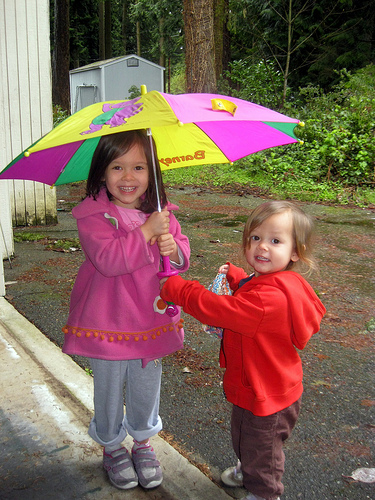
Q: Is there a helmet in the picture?
A: No, there are no helmets.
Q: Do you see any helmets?
A: No, there are no helmets.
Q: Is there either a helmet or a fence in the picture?
A: No, there are no helmets or fences.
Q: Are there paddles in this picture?
A: No, there are no paddles.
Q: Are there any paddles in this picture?
A: No, there are no paddles.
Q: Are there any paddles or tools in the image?
A: No, there are no paddles or tools.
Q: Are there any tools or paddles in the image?
A: No, there are no paddles or tools.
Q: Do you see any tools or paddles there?
A: No, there are no paddles or tools.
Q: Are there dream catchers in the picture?
A: No, there are no dream catchers.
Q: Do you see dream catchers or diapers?
A: No, there are no dream catchers or diapers.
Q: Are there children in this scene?
A: Yes, there is a child.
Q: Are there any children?
A: Yes, there is a child.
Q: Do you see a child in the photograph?
A: Yes, there is a child.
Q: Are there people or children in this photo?
A: Yes, there is a child.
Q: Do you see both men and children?
A: No, there is a child but no men.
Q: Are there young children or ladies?
A: Yes, there is a young child.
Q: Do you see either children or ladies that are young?
A: Yes, the child is young.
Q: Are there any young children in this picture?
A: Yes, there is a young child.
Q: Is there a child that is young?
A: Yes, there is a child that is young.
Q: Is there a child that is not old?
A: Yes, there is an young child.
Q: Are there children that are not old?
A: Yes, there is an young child.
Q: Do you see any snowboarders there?
A: No, there are no snowboarders.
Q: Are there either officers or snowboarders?
A: No, there are no snowboarders or officers.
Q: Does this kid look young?
A: Yes, the kid is young.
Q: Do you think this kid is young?
A: Yes, the kid is young.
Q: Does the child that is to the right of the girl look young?
A: Yes, the child is young.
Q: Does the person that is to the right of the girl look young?
A: Yes, the child is young.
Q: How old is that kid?
A: The kid is young.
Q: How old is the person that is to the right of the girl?
A: The kid is young.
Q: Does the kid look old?
A: No, the kid is young.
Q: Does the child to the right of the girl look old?
A: No, the kid is young.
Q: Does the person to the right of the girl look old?
A: No, the kid is young.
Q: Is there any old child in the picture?
A: No, there is a child but he is young.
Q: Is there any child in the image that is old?
A: No, there is a child but he is young.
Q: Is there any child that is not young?
A: No, there is a child but he is young.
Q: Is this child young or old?
A: The child is young.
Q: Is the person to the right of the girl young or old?
A: The child is young.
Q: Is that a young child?
A: Yes, that is a young child.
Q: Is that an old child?
A: No, that is a young child.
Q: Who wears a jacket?
A: The kid wears a jacket.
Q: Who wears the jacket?
A: The kid wears a jacket.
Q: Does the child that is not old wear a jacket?
A: Yes, the child wears a jacket.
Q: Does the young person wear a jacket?
A: Yes, the child wears a jacket.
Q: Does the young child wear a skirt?
A: No, the child wears a jacket.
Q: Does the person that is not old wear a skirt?
A: No, the child wears a jacket.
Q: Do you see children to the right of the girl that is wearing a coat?
A: Yes, there is a child to the right of the girl.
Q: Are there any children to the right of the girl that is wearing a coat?
A: Yes, there is a child to the right of the girl.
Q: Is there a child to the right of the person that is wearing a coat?
A: Yes, there is a child to the right of the girl.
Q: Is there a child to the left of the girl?
A: No, the child is to the right of the girl.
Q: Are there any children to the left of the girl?
A: No, the child is to the right of the girl.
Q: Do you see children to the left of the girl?
A: No, the child is to the right of the girl.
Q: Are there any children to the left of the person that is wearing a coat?
A: No, the child is to the right of the girl.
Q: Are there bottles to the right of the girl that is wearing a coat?
A: No, there is a child to the right of the girl.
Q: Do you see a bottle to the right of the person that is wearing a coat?
A: No, there is a child to the right of the girl.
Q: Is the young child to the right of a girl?
A: Yes, the kid is to the right of a girl.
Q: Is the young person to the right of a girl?
A: Yes, the kid is to the right of a girl.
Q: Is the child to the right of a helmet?
A: No, the child is to the right of a girl.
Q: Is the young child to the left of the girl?
A: No, the child is to the right of the girl.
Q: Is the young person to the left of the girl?
A: No, the child is to the right of the girl.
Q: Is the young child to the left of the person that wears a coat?
A: No, the child is to the right of the girl.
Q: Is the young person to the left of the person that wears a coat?
A: No, the child is to the right of the girl.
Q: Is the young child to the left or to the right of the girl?
A: The child is to the right of the girl.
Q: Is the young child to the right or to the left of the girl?
A: The child is to the right of the girl.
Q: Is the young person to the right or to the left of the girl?
A: The child is to the right of the girl.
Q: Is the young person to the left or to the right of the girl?
A: The child is to the right of the girl.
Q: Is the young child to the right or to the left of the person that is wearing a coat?
A: The child is to the right of the girl.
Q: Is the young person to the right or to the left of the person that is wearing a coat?
A: The child is to the right of the girl.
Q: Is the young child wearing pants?
A: Yes, the child is wearing pants.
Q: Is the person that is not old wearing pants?
A: Yes, the child is wearing pants.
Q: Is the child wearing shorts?
A: No, the child is wearing pants.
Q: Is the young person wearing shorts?
A: No, the child is wearing pants.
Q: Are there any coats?
A: Yes, there is a coat.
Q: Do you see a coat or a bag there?
A: Yes, there is a coat.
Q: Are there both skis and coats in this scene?
A: No, there is a coat but no skis.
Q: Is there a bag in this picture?
A: No, there are no bags.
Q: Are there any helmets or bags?
A: No, there are no bags or helmets.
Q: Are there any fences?
A: No, there are no fences.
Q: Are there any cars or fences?
A: No, there are no fences or cars.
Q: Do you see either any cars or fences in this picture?
A: No, there are no fences or cars.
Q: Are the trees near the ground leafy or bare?
A: The trees are leafy.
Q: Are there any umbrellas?
A: Yes, there is an umbrella.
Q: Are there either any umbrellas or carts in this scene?
A: Yes, there is an umbrella.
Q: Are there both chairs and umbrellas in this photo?
A: No, there is an umbrella but no chairs.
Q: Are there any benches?
A: No, there are no benches.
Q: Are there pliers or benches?
A: No, there are no benches or pliers.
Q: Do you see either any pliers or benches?
A: No, there are no benches or pliers.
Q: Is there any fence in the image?
A: No, there are no fences.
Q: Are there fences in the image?
A: No, there are no fences.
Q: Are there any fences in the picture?
A: No, there are no fences.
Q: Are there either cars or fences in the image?
A: No, there are no fences or cars.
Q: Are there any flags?
A: No, there are no flags.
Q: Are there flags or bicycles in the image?
A: No, there are no flags or bicycles.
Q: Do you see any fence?
A: No, there are no fences.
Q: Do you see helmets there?
A: No, there are no helmets.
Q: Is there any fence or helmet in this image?
A: No, there are no helmets or fences.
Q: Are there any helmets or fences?
A: No, there are no helmets or fences.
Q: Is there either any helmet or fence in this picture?
A: No, there are no helmets or fences.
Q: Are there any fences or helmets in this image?
A: No, there are no helmets or fences.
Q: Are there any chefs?
A: No, there are no chefs.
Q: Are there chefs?
A: No, there are no chefs.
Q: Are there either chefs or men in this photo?
A: No, there are no chefs or men.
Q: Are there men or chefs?
A: No, there are no chefs or men.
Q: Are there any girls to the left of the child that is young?
A: Yes, there is a girl to the left of the child.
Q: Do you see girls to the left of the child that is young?
A: Yes, there is a girl to the left of the child.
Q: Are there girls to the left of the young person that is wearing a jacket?
A: Yes, there is a girl to the left of the child.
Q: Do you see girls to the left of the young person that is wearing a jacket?
A: Yes, there is a girl to the left of the child.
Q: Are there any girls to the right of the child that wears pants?
A: No, the girl is to the left of the child.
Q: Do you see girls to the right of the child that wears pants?
A: No, the girl is to the left of the child.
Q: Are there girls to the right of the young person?
A: No, the girl is to the left of the child.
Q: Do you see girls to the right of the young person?
A: No, the girl is to the left of the child.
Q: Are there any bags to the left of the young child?
A: No, there is a girl to the left of the kid.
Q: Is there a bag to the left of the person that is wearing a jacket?
A: No, there is a girl to the left of the kid.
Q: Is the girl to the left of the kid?
A: Yes, the girl is to the left of the kid.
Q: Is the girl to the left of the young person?
A: Yes, the girl is to the left of the kid.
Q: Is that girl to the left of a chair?
A: No, the girl is to the left of the kid.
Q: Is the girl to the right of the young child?
A: No, the girl is to the left of the child.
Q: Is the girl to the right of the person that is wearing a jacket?
A: No, the girl is to the left of the child.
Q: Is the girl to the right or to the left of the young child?
A: The girl is to the left of the child.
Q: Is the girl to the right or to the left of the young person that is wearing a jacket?
A: The girl is to the left of the child.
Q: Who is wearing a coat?
A: The girl is wearing a coat.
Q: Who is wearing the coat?
A: The girl is wearing a coat.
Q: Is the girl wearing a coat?
A: Yes, the girl is wearing a coat.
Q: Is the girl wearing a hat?
A: No, the girl is wearing a coat.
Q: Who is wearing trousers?
A: The girl is wearing trousers.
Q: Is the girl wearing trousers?
A: Yes, the girl is wearing trousers.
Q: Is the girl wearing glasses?
A: No, the girl is wearing trousers.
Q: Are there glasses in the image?
A: No, there are no glasses.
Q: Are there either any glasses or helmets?
A: No, there are no glasses or helmets.